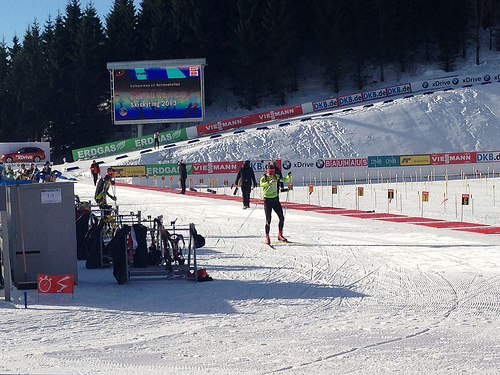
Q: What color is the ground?
A: White.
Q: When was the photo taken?
A: Daytime.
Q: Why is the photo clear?
A: Its during the day.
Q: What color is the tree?
A: Green.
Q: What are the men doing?
A: Skiing.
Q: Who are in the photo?
A: People.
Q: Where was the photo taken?
A: At a ski resort.